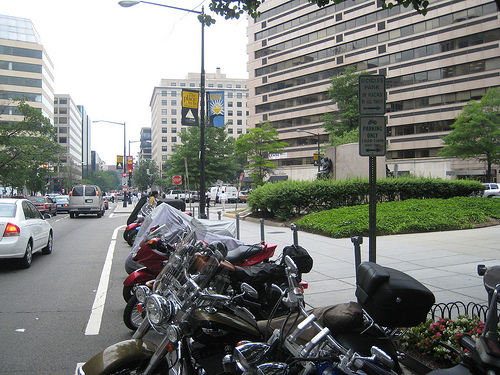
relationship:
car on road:
[3, 198, 62, 270] [0, 196, 139, 371]